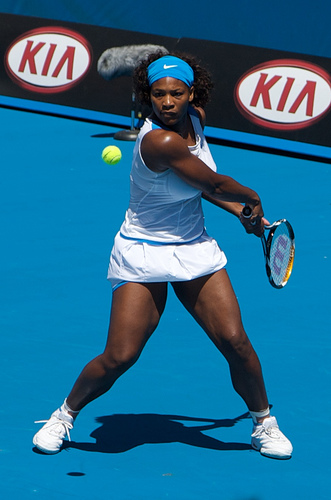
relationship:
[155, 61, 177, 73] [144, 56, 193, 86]
logo sewn on headband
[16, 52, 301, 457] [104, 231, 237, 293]
lady wearing skirt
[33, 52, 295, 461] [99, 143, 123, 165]
lady preparing to hit ball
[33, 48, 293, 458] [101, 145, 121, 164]
tennis player taking her stance to hit ball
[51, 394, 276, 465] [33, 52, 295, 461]
shadow of lady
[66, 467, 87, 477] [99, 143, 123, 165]
shadow of ball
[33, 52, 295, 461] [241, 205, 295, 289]
lady swinging tennis racket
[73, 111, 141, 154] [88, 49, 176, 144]
base on stand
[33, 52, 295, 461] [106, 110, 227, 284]
lady wearing a white dress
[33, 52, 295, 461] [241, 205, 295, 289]
lady holding tennis racket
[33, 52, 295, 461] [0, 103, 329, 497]
lady on court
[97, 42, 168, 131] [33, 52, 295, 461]
furry stool behind lady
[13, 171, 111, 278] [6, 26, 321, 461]
part of a court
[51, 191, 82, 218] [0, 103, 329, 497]
part of a court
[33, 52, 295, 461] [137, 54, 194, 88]
lady wearing head band